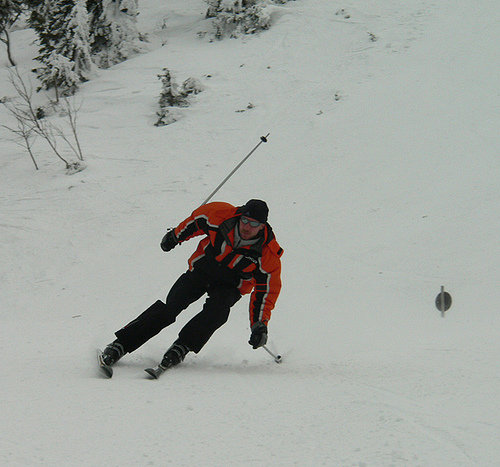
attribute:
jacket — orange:
[175, 202, 281, 313]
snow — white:
[1, 3, 499, 461]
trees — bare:
[1, 0, 321, 177]